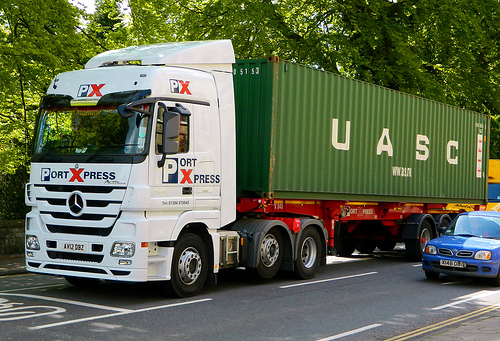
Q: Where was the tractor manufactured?
A: Mercedes.